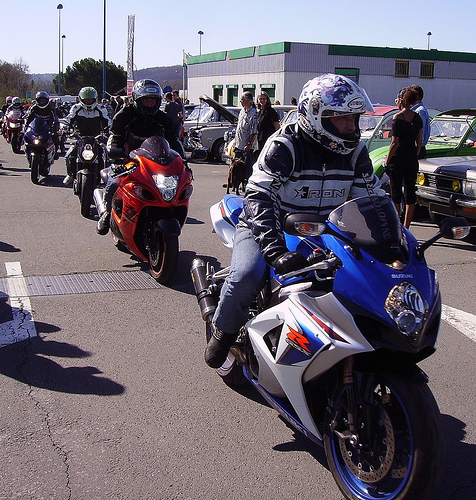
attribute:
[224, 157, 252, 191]
dog — brown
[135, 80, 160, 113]
helmet — black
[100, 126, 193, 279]
motorcycle — red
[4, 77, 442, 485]
motorcylcles — lined up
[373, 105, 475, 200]
car — green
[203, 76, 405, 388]
person — leading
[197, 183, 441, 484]
motorcycle — blue, white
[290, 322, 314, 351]
lettering — orange, red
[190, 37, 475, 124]
building — grey, green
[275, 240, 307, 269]
glove — black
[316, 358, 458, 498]
tire — black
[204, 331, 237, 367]
boot — black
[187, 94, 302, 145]
car — white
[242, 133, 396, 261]
jacket — white, black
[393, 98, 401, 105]
sunglasses — white